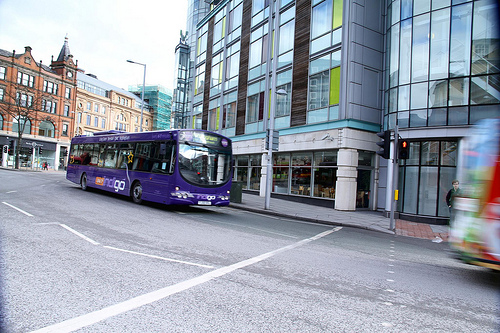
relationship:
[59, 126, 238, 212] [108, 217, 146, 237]
bus on road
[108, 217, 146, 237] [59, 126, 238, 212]
road near bus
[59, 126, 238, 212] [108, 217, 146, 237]
bus travels on road